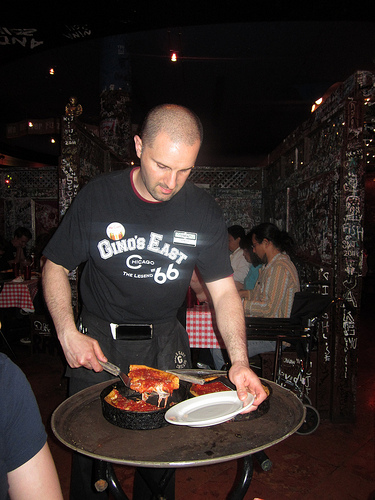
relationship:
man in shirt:
[40, 100, 265, 497] [38, 166, 235, 326]